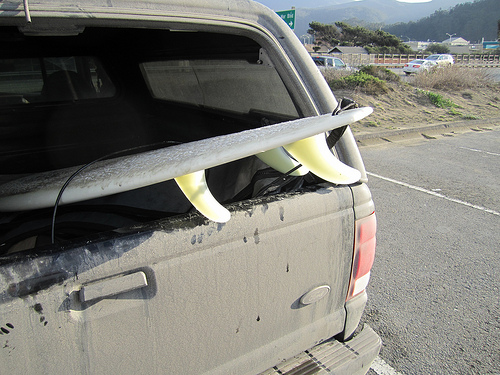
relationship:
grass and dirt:
[346, 71, 390, 97] [333, 88, 459, 135]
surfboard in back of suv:
[0, 97, 373, 225] [1, 1, 384, 373]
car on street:
[402, 56, 438, 77] [306, 54, 499, 78]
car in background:
[402, 56, 438, 77] [259, 0, 499, 90]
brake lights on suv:
[353, 209, 379, 275] [1, 1, 384, 373]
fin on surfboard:
[283, 132, 362, 190] [0, 97, 373, 225]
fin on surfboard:
[173, 171, 234, 225] [0, 97, 373, 225]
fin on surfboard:
[255, 148, 311, 179] [0, 97, 373, 225]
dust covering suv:
[0, 0, 382, 374] [1, 1, 384, 373]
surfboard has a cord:
[0, 97, 373, 225] [31, 137, 183, 244]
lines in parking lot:
[361, 146, 500, 219] [2, 3, 499, 375]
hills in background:
[271, 0, 480, 29] [259, 0, 499, 90]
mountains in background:
[263, 1, 475, 34] [259, 0, 499, 90]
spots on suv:
[252, 230, 262, 245] [1, 1, 384, 373]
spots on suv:
[278, 204, 286, 222] [1, 1, 384, 373]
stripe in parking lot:
[361, 146, 500, 219] [2, 3, 499, 375]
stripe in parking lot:
[448, 137, 499, 160] [2, 3, 499, 375]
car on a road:
[312, 53, 360, 75] [306, 54, 499, 78]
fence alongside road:
[311, 50, 498, 66] [306, 54, 499, 78]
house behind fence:
[307, 43, 368, 55] [311, 50, 498, 66]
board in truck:
[0, 97, 373, 225] [1, 1, 384, 373]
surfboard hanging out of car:
[0, 97, 373, 225] [1, 1, 384, 373]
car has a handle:
[1, 1, 384, 373] [75, 268, 150, 308]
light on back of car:
[353, 209, 379, 275] [1, 1, 384, 373]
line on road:
[361, 146, 500, 219] [354, 122, 499, 371]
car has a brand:
[1, 1, 384, 373] [295, 278, 332, 313]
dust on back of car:
[0, 0, 382, 374] [1, 1, 384, 373]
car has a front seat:
[1, 1, 384, 373] [40, 69, 97, 100]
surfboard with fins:
[0, 97, 373, 225] [164, 133, 363, 225]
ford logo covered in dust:
[295, 278, 332, 313] [294, 283, 332, 308]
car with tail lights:
[402, 56, 438, 77] [402, 61, 420, 70]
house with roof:
[307, 43, 368, 55] [328, 42, 366, 54]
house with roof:
[444, 35, 472, 47] [440, 31, 459, 44]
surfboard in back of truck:
[0, 97, 373, 225] [1, 1, 384, 373]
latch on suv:
[75, 268, 150, 308] [1, 1, 384, 373]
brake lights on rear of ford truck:
[353, 209, 379, 275] [1, 1, 384, 373]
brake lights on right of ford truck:
[353, 209, 379, 275] [1, 1, 384, 373]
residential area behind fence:
[302, 36, 499, 52] [311, 50, 498, 66]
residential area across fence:
[302, 36, 499, 52] [311, 50, 498, 66]